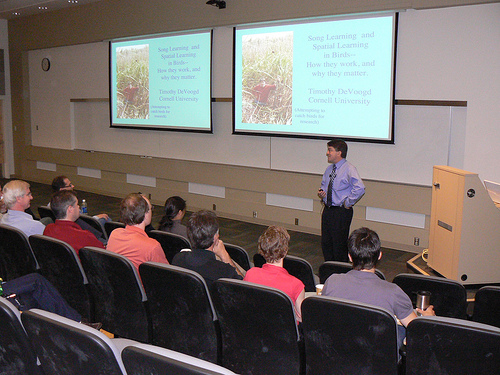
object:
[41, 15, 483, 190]
wall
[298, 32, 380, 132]
writing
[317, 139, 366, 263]
man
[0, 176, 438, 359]
people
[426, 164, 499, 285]
podium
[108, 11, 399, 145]
slide show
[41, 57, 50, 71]
clock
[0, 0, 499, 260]
wall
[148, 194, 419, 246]
outlets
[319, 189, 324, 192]
remote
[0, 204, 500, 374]
seats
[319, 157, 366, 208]
shirt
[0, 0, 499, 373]
room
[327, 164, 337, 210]
purple tie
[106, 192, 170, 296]
man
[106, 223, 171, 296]
orange shirt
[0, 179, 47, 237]
man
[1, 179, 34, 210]
grey hair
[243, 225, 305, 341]
woman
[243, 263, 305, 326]
shirt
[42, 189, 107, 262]
man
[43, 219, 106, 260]
red shirt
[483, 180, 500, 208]
equipment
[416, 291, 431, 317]
thermos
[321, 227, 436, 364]
person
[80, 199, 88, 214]
water bottle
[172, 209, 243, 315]
man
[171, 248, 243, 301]
black shirt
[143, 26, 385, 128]
writing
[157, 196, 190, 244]
man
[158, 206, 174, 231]
pony tail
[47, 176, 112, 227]
man